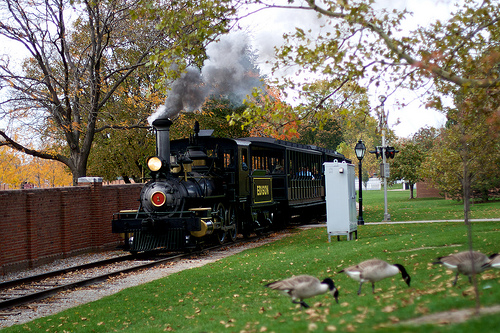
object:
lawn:
[0, 220, 500, 333]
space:
[0, 219, 499, 333]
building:
[416, 170, 499, 200]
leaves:
[379, 302, 399, 314]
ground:
[0, 183, 500, 332]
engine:
[110, 118, 277, 253]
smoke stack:
[151, 118, 173, 170]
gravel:
[129, 275, 133, 278]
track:
[0, 233, 270, 310]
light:
[353, 139, 367, 164]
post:
[356, 161, 364, 226]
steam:
[148, 30, 278, 122]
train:
[110, 121, 353, 253]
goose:
[335, 256, 411, 296]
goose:
[431, 249, 500, 288]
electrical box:
[323, 158, 359, 243]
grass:
[0, 219, 500, 333]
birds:
[261, 273, 339, 309]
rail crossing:
[352, 176, 382, 192]